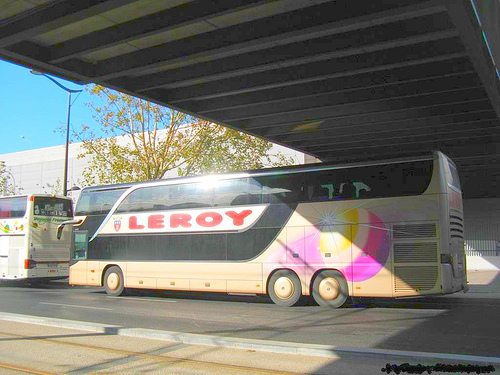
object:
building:
[0, 119, 220, 196]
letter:
[170, 213, 193, 228]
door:
[73, 228, 86, 260]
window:
[384, 160, 434, 197]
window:
[306, 167, 344, 203]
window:
[214, 177, 256, 207]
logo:
[129, 209, 253, 229]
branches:
[71, 82, 275, 185]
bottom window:
[125, 236, 155, 261]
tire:
[265, 268, 302, 307]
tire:
[101, 264, 124, 296]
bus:
[68, 150, 470, 309]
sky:
[6, 93, 60, 135]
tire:
[311, 267, 352, 308]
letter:
[147, 214, 165, 228]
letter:
[224, 208, 253, 225]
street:
[0, 268, 499, 357]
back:
[27, 193, 74, 279]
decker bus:
[0, 193, 74, 284]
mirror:
[56, 223, 65, 240]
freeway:
[0, 7, 499, 147]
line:
[38, 301, 113, 311]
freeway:
[0, 277, 499, 358]